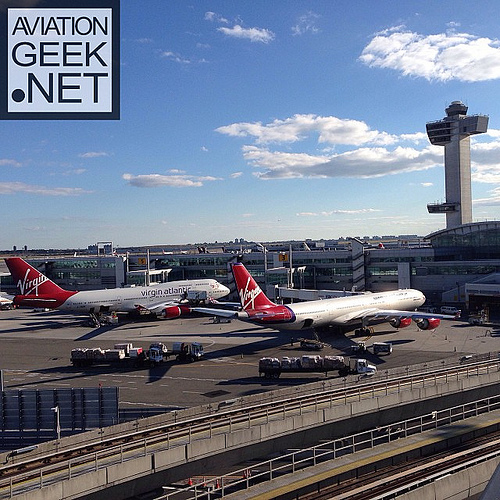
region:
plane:
[11, 251, 248, 336]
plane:
[230, 251, 428, 338]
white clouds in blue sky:
[161, 44, 219, 95]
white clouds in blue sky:
[187, 9, 257, 116]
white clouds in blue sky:
[263, 143, 307, 174]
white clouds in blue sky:
[267, 130, 372, 188]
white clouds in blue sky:
[320, 103, 387, 171]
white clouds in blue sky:
[341, 27, 395, 78]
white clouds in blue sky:
[413, 33, 464, 80]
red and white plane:
[6, 248, 218, 318]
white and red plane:
[227, 270, 424, 337]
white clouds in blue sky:
[159, 14, 226, 80]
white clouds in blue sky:
[224, 104, 279, 176]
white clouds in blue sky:
[257, 110, 319, 199]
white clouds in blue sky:
[326, 83, 392, 224]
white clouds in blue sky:
[110, 122, 169, 201]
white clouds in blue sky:
[23, 136, 76, 185]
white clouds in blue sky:
[329, 17, 384, 58]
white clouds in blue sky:
[384, 17, 448, 84]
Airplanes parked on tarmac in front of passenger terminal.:
[3, 248, 463, 349]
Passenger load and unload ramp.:
[278, 280, 371, 304]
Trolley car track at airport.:
[364, 436, 487, 491]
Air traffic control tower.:
[418, 90, 498, 230]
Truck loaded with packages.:
[253, 350, 376, 380]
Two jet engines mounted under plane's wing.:
[387, 314, 449, 337]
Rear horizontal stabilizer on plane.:
[190, 303, 242, 323]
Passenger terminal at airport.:
[262, 222, 499, 297]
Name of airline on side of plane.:
[137, 283, 200, 299]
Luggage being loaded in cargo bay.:
[81, 301, 126, 331]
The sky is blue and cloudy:
[216, 42, 379, 202]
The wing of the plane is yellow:
[205, 258, 302, 343]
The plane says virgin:
[9, 258, 78, 323]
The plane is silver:
[300, 290, 455, 322]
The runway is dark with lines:
[122, 355, 204, 420]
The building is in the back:
[323, 241, 495, 357]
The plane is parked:
[0, 243, 240, 342]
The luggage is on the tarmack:
[45, 327, 227, 386]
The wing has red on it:
[384, 303, 444, 332]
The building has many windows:
[296, 244, 460, 284]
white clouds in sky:
[208, 93, 343, 185]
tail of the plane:
[218, 266, 281, 324]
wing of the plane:
[373, 290, 432, 342]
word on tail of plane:
[218, 275, 265, 320]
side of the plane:
[300, 293, 419, 333]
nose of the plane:
[199, 271, 239, 314]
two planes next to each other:
[56, 249, 413, 378]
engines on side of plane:
[391, 302, 441, 345]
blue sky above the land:
[226, 181, 276, 211]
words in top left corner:
[8, 8, 128, 128]